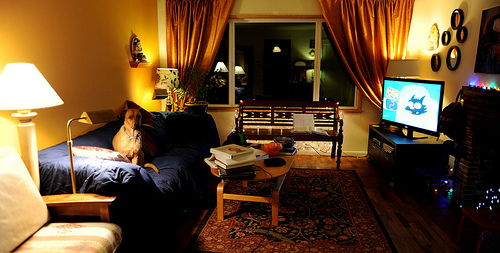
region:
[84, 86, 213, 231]
dog sitting on a couch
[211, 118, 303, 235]
coffee table with a pile of books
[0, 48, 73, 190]
lamp with a white shade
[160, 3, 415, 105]
window with orange curtains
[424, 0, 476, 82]
five round mirrors on a wall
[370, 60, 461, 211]
tv on a tv stand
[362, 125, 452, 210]
small black tv stand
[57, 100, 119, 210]
gold desk lamp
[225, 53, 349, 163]
bench near a window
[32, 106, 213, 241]
couch with a blue slipcover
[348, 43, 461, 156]
flat screen tv on table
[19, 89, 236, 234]
dog sitting on couch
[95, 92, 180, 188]
brown dog sitting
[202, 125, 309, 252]
brown wooden coffee table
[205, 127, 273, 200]
books on coffee table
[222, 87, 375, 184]
bench in living room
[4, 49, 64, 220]
lamp on the side of chair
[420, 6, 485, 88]
frames on the wall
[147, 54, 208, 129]
lamp in the corner of living room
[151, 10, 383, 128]
windows in the living room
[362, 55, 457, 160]
Flat screen tv on stand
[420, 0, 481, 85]
framed pictures on wall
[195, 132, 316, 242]
brown wooden coffee table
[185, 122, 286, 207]
books on table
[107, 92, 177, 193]
brown dog sitting on couch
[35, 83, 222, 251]
blue couch cover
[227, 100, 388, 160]
bench in the living room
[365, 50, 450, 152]
floor lamp in the corner of living room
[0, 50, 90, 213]
lamp in between couches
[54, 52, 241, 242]
a dog on a couch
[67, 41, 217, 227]
a dog on a blue couch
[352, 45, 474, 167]
a television turned on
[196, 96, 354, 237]
books on a table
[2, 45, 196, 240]
a lamp next to the couch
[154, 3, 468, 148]
a window with curtains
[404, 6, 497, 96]
decorations on the wall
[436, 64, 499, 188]
a fireplace with lights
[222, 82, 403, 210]
a bench in front of the window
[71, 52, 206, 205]
a dog with a colar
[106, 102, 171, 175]
a large brown great dane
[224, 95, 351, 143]
Park-style bench in living room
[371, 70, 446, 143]
flat screen television on stand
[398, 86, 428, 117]
"Scratchy" the cat from The Simpsons' "Itchy and Scratchy"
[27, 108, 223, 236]
A couch covered in a blue blanket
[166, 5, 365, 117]
A large rectangular window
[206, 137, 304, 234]
coffee table with many things on it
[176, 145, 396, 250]
floor rug on hardwood floor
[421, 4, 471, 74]
several oval picture frames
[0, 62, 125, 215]
Two lamps of differing style